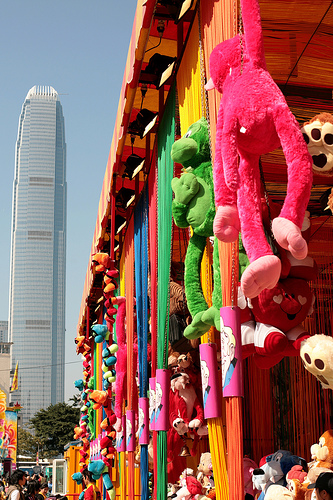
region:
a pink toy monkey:
[198, 29, 302, 282]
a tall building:
[10, 72, 93, 440]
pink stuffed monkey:
[204, 1, 312, 297]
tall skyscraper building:
[5, 82, 72, 416]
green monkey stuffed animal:
[166, 110, 226, 337]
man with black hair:
[7, 467, 29, 499]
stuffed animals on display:
[175, 429, 328, 497]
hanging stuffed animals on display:
[68, 4, 326, 497]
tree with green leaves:
[31, 399, 78, 455]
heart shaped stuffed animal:
[247, 276, 314, 352]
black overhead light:
[139, 43, 175, 90]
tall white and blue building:
[11, 77, 68, 429]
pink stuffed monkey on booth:
[210, 46, 274, 194]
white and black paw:
[308, 352, 322, 366]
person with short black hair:
[7, 468, 26, 488]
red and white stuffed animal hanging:
[172, 382, 206, 446]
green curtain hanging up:
[152, 446, 166, 471]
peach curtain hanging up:
[235, 423, 239, 462]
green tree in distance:
[54, 415, 76, 450]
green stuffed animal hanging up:
[165, 150, 203, 199]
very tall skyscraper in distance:
[41, 358, 63, 391]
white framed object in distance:
[52, 461, 76, 493]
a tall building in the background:
[10, 75, 68, 451]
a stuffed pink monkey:
[209, 29, 325, 284]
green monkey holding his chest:
[162, 110, 259, 335]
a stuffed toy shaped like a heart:
[252, 279, 313, 370]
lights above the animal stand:
[78, 2, 187, 338]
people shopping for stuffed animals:
[0, 463, 99, 497]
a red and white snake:
[86, 381, 124, 471]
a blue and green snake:
[88, 318, 123, 394]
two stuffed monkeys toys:
[150, 25, 317, 338]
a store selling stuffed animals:
[73, 6, 327, 495]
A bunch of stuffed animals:
[146, 428, 329, 498]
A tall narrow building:
[5, 78, 73, 456]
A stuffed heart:
[242, 279, 320, 345]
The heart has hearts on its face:
[248, 280, 316, 362]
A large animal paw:
[297, 327, 331, 392]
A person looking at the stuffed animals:
[2, 464, 30, 499]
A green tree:
[33, 402, 81, 449]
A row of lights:
[105, 125, 151, 260]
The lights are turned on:
[103, 45, 171, 246]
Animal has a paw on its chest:
[155, 115, 224, 332]